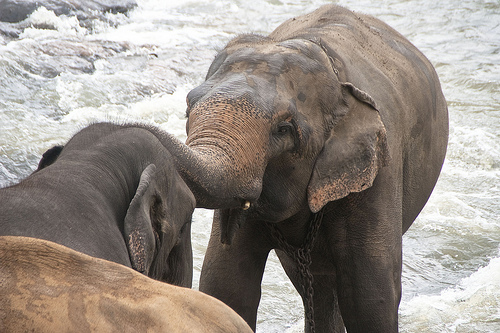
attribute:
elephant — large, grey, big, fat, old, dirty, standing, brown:
[157, 29, 487, 285]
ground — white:
[43, 14, 181, 101]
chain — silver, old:
[294, 247, 325, 325]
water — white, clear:
[448, 22, 495, 224]